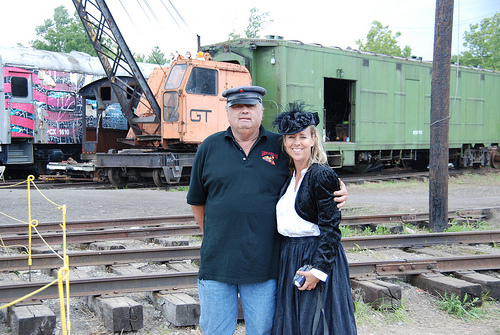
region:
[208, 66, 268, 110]
black hat worn by man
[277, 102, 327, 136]
black hat worn by woman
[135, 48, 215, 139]
orange crane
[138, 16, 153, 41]
white clouds in blue sky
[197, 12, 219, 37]
white clouds in blue sky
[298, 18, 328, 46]
white clouds in blue sky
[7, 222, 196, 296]
empty railroad tracks on wooden blocks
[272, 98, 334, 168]
a lady wearing a hat with feathers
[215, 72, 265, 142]
a man wearing a brimmed cap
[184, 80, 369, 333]
a man with his arm around a lady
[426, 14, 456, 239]
pole in the middle of the tracks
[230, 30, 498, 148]
green train car on track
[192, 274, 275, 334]
a man wearing blue jeans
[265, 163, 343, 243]
a woman wearing a white blouse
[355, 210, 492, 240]
grass between railroad tracks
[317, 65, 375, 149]
open door on green train car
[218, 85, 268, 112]
a man wearing a leather hat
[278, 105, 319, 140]
a woman wearing a black hat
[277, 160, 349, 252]
a woman wearing a black jacket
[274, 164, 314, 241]
a woman wearing a white shirt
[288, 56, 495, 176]
a green train car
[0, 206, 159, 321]
two sets of train tracks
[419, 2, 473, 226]
a wood pole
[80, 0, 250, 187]
a yellow crane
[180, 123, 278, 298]
a man wearing a black shirt with a logo on it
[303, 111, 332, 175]
a woman with blonde hair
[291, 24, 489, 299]
a train on the track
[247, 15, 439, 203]
a train on train track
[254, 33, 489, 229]
a green train on track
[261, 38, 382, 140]
a green train on train track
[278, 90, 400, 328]
a woman wearing a white shirt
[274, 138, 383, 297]
a woman wearing a black skirt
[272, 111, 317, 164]
a woman wearing a hat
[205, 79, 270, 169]
a man ewaring a hat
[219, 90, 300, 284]
a man wearing a black shirt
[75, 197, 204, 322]
Two sets of railroad tracks.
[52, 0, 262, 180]
Orange and black crane.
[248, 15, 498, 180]
Green cargo box trailer.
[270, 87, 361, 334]
Woman in black and white period clothing.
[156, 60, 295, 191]
Man wearing train conductor cap.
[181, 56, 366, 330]
Man with arm around woman.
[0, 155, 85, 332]
Yellow roped off area.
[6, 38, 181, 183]
Multi colored passenger car.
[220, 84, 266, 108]
A black hat on a man.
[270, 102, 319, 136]
A large black hat on a woman.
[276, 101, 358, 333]
A woman in white and black with a big hat.